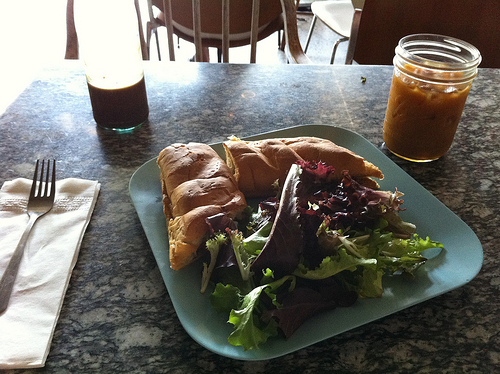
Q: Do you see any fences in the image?
A: No, there are no fences.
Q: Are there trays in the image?
A: No, there are no trays.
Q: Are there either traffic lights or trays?
A: No, there are no trays or traffic lights.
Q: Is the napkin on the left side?
A: Yes, the napkin is on the left of the image.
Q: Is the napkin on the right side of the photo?
A: No, the napkin is on the left of the image.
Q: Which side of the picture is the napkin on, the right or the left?
A: The napkin is on the left of the image.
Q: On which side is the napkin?
A: The napkin is on the left of the image.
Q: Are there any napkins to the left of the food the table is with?
A: Yes, there is a napkin to the left of the food.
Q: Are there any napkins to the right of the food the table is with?
A: No, the napkin is to the left of the food.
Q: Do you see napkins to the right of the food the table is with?
A: No, the napkin is to the left of the food.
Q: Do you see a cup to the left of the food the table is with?
A: No, there is a napkin to the left of the food.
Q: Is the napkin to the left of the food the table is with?
A: Yes, the napkin is to the left of the food.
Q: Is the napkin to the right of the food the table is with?
A: No, the napkin is to the left of the food.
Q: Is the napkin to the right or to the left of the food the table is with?
A: The napkin is to the left of the food.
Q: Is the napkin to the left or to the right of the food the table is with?
A: The napkin is to the left of the food.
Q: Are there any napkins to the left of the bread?
A: Yes, there is a napkin to the left of the bread.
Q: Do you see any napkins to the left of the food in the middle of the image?
A: Yes, there is a napkin to the left of the bread.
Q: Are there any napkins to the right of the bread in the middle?
A: No, the napkin is to the left of the bread.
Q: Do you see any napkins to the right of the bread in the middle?
A: No, the napkin is to the left of the bread.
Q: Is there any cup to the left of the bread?
A: No, there is a napkin to the left of the bread.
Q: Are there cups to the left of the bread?
A: No, there is a napkin to the left of the bread.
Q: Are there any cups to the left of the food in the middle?
A: No, there is a napkin to the left of the bread.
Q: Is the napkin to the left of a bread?
A: Yes, the napkin is to the left of a bread.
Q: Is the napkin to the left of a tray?
A: No, the napkin is to the left of a bread.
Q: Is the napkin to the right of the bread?
A: No, the napkin is to the left of the bread.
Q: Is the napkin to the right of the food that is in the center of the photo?
A: No, the napkin is to the left of the bread.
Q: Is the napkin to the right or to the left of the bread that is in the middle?
A: The napkin is to the left of the bread.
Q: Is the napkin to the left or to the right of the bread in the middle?
A: The napkin is to the left of the bread.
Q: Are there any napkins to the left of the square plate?
A: Yes, there is a napkin to the left of the plate.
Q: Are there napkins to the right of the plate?
A: No, the napkin is to the left of the plate.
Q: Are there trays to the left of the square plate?
A: No, there is a napkin to the left of the plate.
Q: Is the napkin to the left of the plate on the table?
A: Yes, the napkin is to the left of the plate.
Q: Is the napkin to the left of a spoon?
A: No, the napkin is to the left of the plate.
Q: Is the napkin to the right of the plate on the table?
A: No, the napkin is to the left of the plate.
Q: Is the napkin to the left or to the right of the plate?
A: The napkin is to the left of the plate.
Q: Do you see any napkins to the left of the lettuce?
A: Yes, there is a napkin to the left of the lettuce.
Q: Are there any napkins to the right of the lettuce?
A: No, the napkin is to the left of the lettuce.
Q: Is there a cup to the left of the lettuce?
A: No, there is a napkin to the left of the lettuce.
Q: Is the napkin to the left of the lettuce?
A: Yes, the napkin is to the left of the lettuce.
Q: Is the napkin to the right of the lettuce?
A: No, the napkin is to the left of the lettuce.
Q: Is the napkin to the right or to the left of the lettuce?
A: The napkin is to the left of the lettuce.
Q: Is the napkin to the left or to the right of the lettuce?
A: The napkin is to the left of the lettuce.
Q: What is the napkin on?
A: The napkin is on the table.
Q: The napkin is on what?
A: The napkin is on the table.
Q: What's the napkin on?
A: The napkin is on the table.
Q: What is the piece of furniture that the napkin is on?
A: The piece of furniture is a table.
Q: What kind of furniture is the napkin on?
A: The napkin is on the table.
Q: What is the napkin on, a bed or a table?
A: The napkin is on a table.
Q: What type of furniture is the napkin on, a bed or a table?
A: The napkin is on a table.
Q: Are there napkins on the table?
A: Yes, there is a napkin on the table.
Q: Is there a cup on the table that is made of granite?
A: No, there is a napkin on the table.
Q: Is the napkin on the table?
A: Yes, the napkin is on the table.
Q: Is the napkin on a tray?
A: No, the napkin is on the table.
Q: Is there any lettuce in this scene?
A: Yes, there is lettuce.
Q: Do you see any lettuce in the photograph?
A: Yes, there is lettuce.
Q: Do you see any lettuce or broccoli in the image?
A: Yes, there is lettuce.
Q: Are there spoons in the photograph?
A: No, there are no spoons.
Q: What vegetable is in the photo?
A: The vegetable is lettuce.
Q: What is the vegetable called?
A: The vegetable is lettuce.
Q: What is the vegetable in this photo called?
A: The vegetable is lettuce.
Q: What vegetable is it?
A: The vegetable is lettuce.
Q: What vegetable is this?
A: This is lettuce.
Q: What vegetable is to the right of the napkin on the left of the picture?
A: The vegetable is lettuce.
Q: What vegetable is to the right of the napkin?
A: The vegetable is lettuce.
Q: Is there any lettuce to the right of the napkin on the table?
A: Yes, there is lettuce to the right of the napkin.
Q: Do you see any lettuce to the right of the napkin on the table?
A: Yes, there is lettuce to the right of the napkin.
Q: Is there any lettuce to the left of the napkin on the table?
A: No, the lettuce is to the right of the napkin.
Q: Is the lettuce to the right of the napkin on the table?
A: Yes, the lettuce is to the right of the napkin.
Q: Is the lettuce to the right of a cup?
A: No, the lettuce is to the right of the napkin.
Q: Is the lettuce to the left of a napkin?
A: No, the lettuce is to the right of a napkin.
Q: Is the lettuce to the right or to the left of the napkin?
A: The lettuce is to the right of the napkin.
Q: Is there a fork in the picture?
A: Yes, there is a fork.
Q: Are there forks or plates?
A: Yes, there is a fork.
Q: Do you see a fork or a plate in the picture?
A: Yes, there is a fork.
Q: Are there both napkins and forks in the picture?
A: Yes, there are both a fork and a napkin.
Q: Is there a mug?
A: No, there are no mugs.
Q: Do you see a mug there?
A: No, there are no mugs.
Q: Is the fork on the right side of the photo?
A: No, the fork is on the left of the image.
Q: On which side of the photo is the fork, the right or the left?
A: The fork is on the left of the image.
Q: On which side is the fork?
A: The fork is on the left of the image.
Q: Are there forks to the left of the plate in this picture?
A: Yes, there is a fork to the left of the plate.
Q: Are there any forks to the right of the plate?
A: No, the fork is to the left of the plate.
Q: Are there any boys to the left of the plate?
A: No, there is a fork to the left of the plate.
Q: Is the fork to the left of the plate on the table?
A: Yes, the fork is to the left of the plate.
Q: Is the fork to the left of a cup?
A: No, the fork is to the left of the plate.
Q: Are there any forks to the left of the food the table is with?
A: Yes, there is a fork to the left of the food.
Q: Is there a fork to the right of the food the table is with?
A: No, the fork is to the left of the food.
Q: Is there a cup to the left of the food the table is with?
A: No, there is a fork to the left of the food.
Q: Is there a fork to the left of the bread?
A: Yes, there is a fork to the left of the bread.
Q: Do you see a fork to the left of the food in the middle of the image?
A: Yes, there is a fork to the left of the bread.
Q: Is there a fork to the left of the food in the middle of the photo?
A: Yes, there is a fork to the left of the bread.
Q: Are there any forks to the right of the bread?
A: No, the fork is to the left of the bread.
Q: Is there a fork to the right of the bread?
A: No, the fork is to the left of the bread.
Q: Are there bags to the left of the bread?
A: No, there is a fork to the left of the bread.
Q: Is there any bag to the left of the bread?
A: No, there is a fork to the left of the bread.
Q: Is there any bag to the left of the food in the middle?
A: No, there is a fork to the left of the bread.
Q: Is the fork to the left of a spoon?
A: No, the fork is to the left of the bread.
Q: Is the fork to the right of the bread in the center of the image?
A: No, the fork is to the left of the bread.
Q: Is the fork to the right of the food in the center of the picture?
A: No, the fork is to the left of the bread.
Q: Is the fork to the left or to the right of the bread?
A: The fork is to the left of the bread.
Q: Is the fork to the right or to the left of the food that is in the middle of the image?
A: The fork is to the left of the bread.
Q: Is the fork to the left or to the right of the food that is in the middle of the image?
A: The fork is to the left of the bread.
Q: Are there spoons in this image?
A: No, there are no spoons.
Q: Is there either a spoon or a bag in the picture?
A: No, there are no spoons or bags.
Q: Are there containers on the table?
A: Yes, there is a container on the table.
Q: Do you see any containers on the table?
A: Yes, there is a container on the table.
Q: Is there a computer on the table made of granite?
A: No, there is a container on the table.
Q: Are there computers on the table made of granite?
A: No, there is a container on the table.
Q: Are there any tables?
A: Yes, there is a table.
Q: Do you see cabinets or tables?
A: Yes, there is a table.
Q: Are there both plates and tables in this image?
A: Yes, there are both a table and a plate.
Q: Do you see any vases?
A: No, there are no vases.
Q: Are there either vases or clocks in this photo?
A: No, there are no vases or clocks.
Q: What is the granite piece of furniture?
A: The piece of furniture is a table.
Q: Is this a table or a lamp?
A: This is a table.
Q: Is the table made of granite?
A: Yes, the table is made of granite.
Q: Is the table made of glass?
A: No, the table is made of granite.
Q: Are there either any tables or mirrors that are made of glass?
A: No, there is a table but it is made of granite.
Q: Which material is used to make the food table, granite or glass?
A: The table is made of granite.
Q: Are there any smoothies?
A: No, there are no smoothies.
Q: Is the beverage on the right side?
A: Yes, the beverage is on the right of the image.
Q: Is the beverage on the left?
A: No, the beverage is on the right of the image.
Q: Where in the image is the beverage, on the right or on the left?
A: The beverage is on the right of the image.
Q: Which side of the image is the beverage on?
A: The beverage is on the right of the image.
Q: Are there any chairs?
A: Yes, there is a chair.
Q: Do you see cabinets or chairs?
A: Yes, there is a chair.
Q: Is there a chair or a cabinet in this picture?
A: Yes, there is a chair.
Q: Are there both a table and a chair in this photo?
A: Yes, there are both a chair and a table.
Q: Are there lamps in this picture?
A: No, there are no lamps.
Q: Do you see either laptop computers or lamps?
A: No, there are no lamps or laptop computers.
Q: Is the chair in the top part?
A: Yes, the chair is in the top of the image.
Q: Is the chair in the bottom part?
A: No, the chair is in the top of the image.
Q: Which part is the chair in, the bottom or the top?
A: The chair is in the top of the image.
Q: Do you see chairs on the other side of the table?
A: Yes, there is a chair on the other side of the table.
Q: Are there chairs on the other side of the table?
A: Yes, there is a chair on the other side of the table.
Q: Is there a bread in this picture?
A: Yes, there is a bread.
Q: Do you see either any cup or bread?
A: Yes, there is a bread.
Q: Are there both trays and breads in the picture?
A: No, there is a bread but no trays.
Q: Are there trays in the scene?
A: No, there are no trays.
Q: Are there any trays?
A: No, there are no trays.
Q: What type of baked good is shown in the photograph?
A: The baked good is a bread.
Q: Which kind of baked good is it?
A: The food is a bread.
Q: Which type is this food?
A: This is a bread.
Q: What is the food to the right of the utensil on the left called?
A: The food is a bread.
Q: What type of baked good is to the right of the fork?
A: The food is a bread.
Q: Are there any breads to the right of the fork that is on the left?
A: Yes, there is a bread to the right of the fork.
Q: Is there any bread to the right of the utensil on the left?
A: Yes, there is a bread to the right of the fork.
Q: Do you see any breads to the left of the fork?
A: No, the bread is to the right of the fork.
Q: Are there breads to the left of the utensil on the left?
A: No, the bread is to the right of the fork.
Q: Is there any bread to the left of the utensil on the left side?
A: No, the bread is to the right of the fork.